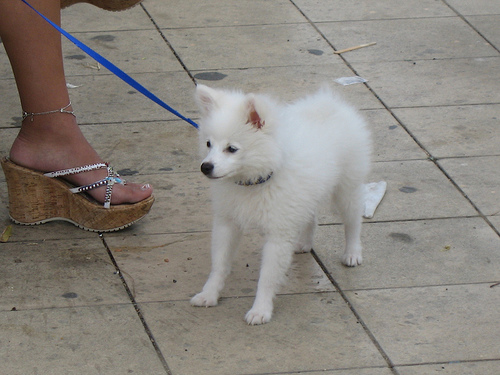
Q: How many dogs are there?
A: One.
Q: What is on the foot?
A: A shoe.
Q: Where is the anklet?
A: On the ankle.